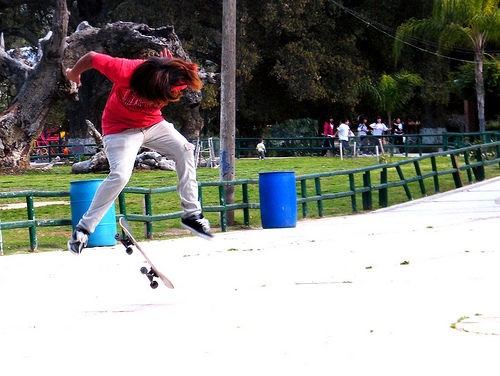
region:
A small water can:
[256, 170, 298, 229]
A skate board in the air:
[114, 210, 183, 302]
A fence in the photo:
[328, 163, 378, 195]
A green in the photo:
[283, 152, 316, 172]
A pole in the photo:
[216, 62, 248, 172]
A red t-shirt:
[103, 59, 132, 140]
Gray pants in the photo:
[102, 131, 144, 218]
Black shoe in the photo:
[68, 229, 90, 255]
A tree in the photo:
[282, 26, 342, 92]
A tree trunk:
[474, 49, 489, 123]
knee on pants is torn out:
[166, 129, 209, 181]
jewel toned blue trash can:
[258, 162, 298, 229]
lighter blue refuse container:
[66, 176, 118, 248]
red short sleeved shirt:
[88, 51, 196, 136]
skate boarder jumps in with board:
[57, 55, 217, 287]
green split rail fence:
[8, 135, 498, 250]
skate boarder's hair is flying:
[128, 50, 193, 105]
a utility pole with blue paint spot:
[216, 0, 238, 232]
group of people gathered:
[313, 114, 405, 154]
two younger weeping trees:
[350, 0, 499, 155]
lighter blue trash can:
[68, 176, 115, 247]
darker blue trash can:
[258, 169, 298, 230]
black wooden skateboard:
[114, 213, 175, 291]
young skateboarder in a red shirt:
[66, 44, 215, 256]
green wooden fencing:
[0, 126, 499, 253]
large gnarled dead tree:
[0, 0, 221, 175]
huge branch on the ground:
[68, 118, 221, 173]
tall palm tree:
[391, 0, 498, 152]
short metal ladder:
[193, 134, 220, 168]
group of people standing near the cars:
[318, 115, 408, 157]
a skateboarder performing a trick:
[61, 46, 216, 289]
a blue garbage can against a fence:
[257, 170, 299, 226]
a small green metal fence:
[3, 139, 498, 254]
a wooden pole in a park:
[218, 0, 239, 227]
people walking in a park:
[321, 113, 407, 157]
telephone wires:
[334, 2, 499, 67]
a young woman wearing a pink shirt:
[89, 53, 191, 136]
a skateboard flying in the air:
[113, 215, 175, 292]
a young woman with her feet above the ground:
[63, 48, 213, 253]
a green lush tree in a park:
[393, 0, 499, 150]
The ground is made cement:
[208, 254, 465, 360]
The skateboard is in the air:
[113, 209, 175, 296]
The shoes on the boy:
[65, 210, 215, 253]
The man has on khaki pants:
[75, 118, 204, 232]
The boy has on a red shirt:
[92, 50, 199, 137]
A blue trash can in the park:
[248, 167, 306, 231]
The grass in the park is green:
[248, 160, 400, 206]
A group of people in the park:
[318, 105, 415, 160]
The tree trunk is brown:
[0, 5, 180, 193]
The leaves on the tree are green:
[263, 4, 497, 70]